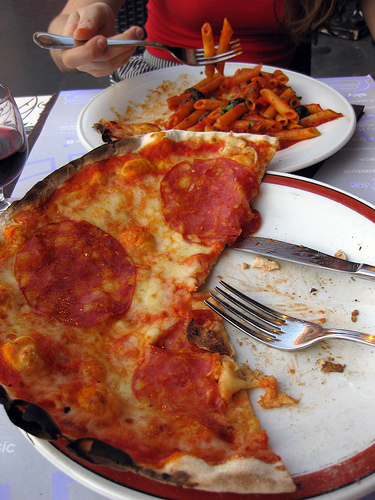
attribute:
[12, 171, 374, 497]
plate — red, white, black, Round 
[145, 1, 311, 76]
shirt — red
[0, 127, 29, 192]
wine — red wine, drinking wine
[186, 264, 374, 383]
fork — metal 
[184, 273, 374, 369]
fork — silver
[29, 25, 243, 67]
fork — metal 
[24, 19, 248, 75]
fork — metal 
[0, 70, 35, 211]
glass — clear 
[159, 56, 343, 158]
noodles — Round 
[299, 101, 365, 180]
napkin — black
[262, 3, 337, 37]
hair — long, Brown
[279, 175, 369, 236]
plate — white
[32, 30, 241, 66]
fork — silver 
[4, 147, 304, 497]
pizza — pepperoni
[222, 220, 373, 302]
knife — silver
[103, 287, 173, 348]
cheese — mega cheese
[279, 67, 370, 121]
plate — rigatoni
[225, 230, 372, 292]
knife — silver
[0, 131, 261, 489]
pizza — eaten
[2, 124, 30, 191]
red wine — red 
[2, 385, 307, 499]
crust — burnt 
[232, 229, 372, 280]
knife — metal 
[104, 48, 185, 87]
bottoms — black , white , stripe 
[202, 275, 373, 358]
fork — silver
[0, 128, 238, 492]
crust — burnt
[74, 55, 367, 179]
plate —  white , white 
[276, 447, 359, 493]
rim — burgandy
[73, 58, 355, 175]
dish — wish